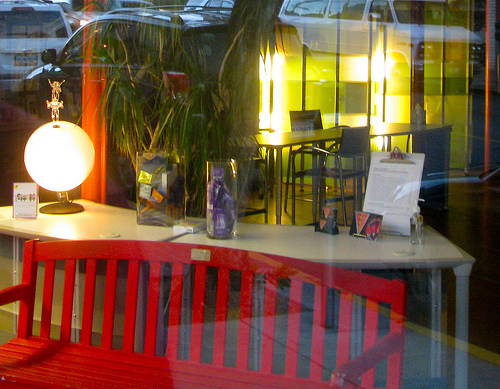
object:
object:
[46, 78, 65, 122]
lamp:
[23, 79, 95, 216]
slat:
[38, 254, 57, 340]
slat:
[143, 260, 161, 355]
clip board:
[360, 146, 426, 235]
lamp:
[23, 119, 95, 194]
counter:
[0, 198, 477, 388]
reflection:
[17, 7, 302, 174]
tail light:
[158, 67, 195, 102]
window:
[0, 0, 499, 388]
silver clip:
[381, 146, 416, 164]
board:
[361, 146, 426, 244]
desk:
[219, 122, 453, 231]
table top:
[2, 185, 478, 290]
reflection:
[276, 0, 483, 97]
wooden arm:
[331, 330, 416, 388]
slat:
[235, 269, 255, 369]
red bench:
[1, 239, 408, 389]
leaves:
[157, 103, 188, 137]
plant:
[43, 0, 286, 220]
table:
[0, 198, 476, 389]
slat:
[165, 264, 183, 357]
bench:
[1, 238, 409, 388]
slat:
[212, 259, 231, 368]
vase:
[135, 150, 187, 228]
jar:
[205, 158, 239, 239]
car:
[0, 0, 73, 96]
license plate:
[14, 51, 38, 66]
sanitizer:
[410, 196, 425, 245]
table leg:
[450, 261, 473, 388]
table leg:
[429, 263, 444, 385]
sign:
[191, 247, 211, 261]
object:
[137, 146, 188, 229]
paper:
[361, 150, 425, 237]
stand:
[39, 201, 84, 214]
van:
[2, 0, 76, 96]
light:
[260, 44, 399, 151]